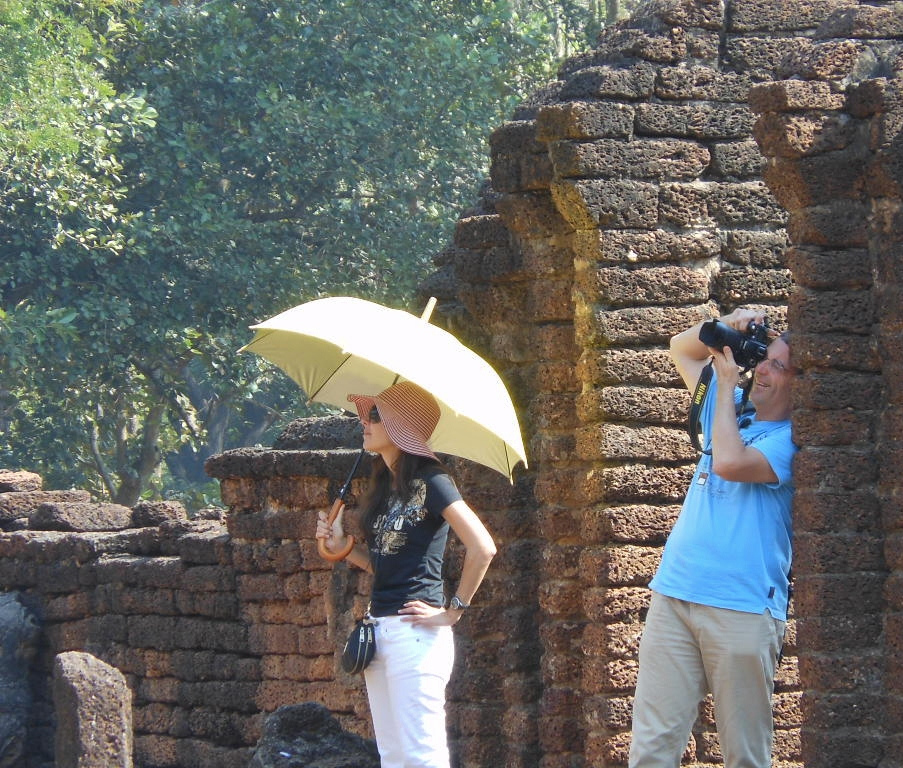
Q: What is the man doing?
A: Looking through the camera's lense.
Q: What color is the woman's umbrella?
A: Yellow.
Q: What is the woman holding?
A: A yellow umbrella.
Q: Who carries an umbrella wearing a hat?
A: A woman.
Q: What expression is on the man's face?
A: A smile.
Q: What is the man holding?
A: A camera.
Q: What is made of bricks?
A: The wall.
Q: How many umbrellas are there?
A: One.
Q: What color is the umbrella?
A: Yellow.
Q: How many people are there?
A: Two.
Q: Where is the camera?
A: The man's hand.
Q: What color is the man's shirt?
A: Blue.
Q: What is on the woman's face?
A: Glasses.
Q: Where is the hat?
A: The woman's head.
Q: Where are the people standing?
A: Near a wall.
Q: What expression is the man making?
A: Smiling.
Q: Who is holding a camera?
A: Man in blue shirt.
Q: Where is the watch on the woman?
A: On her wrist.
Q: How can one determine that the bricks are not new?
A: Weathering.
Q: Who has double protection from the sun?
A: The woman with a hat and umbrella.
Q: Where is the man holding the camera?
A: Against his eye.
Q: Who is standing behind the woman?
A: Man in blue shirt.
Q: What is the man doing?
A: Taking a picture.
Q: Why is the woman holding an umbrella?
A: Protection from the sun.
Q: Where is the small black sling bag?
A: Against the woman's white pants.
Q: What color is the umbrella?
A: Yellow.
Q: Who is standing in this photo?
A: A man and woman.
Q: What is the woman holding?
A: An umbrella.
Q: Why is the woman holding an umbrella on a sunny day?
A: She is using the umbrella to shield herself from the sun.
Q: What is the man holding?
A: A camera.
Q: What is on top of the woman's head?
A: A hat.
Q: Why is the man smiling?
A: He is happy to be taking a picture.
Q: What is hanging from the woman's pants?
A: A purse.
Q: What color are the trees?
A: Green.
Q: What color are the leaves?
A: Green.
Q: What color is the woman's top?
A: Black.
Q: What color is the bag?
A: Black.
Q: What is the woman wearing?
A: Watch.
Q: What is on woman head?
A: Hat.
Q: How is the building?
A: Not finished.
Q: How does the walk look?
A: Old.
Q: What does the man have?
A: Camera.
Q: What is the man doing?
A: Looking.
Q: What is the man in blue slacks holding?
A: Camera.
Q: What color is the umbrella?
A: White.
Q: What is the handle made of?
A: Wood.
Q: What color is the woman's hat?
A: Red.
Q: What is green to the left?
A: Trees.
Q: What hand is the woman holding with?
A: Right.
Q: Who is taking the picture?
A: A man.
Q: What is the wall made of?
A: Mud brick.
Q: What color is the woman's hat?
A: Pink.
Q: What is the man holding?
A: Camera.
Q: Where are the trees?
A: In background.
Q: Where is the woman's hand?
A: On hip.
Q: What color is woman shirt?
A: Black.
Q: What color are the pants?
A: White.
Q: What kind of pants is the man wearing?
A: Khaki.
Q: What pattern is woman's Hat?
A: Striped.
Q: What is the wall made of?
A: Brick.